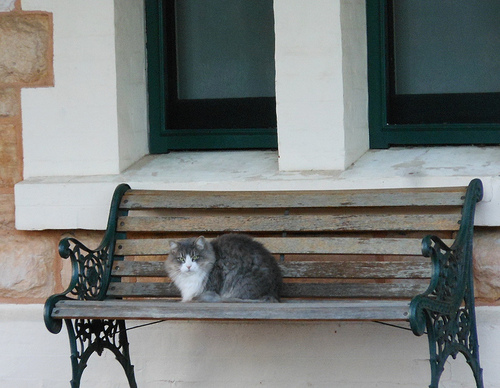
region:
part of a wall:
[368, 179, 384, 193]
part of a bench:
[317, 300, 332, 322]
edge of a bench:
[325, 290, 336, 305]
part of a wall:
[328, 183, 350, 220]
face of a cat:
[183, 254, 205, 275]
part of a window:
[409, 113, 420, 137]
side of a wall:
[326, 140, 337, 157]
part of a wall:
[286, 343, 301, 360]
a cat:
[163, 230, 286, 305]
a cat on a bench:
[163, 232, 289, 307]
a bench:
[43, 180, 494, 386]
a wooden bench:
[36, 180, 490, 385]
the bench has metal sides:
[48, 180, 485, 386]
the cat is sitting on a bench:
[163, 228, 290, 308]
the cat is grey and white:
[162, 229, 289, 306]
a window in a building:
[118, 0, 499, 185]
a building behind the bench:
[3, 5, 492, 386]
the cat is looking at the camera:
[158, 226, 299, 303]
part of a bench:
[407, 275, 427, 298]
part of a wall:
[321, 130, 328, 138]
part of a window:
[388, 124, 411, 186]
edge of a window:
[373, 152, 382, 167]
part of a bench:
[346, 245, 377, 281]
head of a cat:
[193, 253, 222, 268]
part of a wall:
[313, 106, 338, 178]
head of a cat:
[251, 265, 264, 283]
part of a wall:
[108, 145, 126, 152]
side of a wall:
[327, 146, 344, 161]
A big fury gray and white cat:
[163, 228, 293, 306]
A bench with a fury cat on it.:
[32, 180, 495, 387]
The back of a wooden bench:
[25, 178, 498, 242]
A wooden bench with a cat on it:
[27, 167, 462, 387]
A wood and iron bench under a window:
[12, 186, 487, 386]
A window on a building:
[103, 4, 293, 179]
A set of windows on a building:
[90, 3, 498, 156]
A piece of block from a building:
[5, 234, 55, 296]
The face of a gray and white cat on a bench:
[162, 233, 211, 278]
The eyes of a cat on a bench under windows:
[171, 252, 209, 264]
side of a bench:
[436, 310, 446, 334]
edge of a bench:
[376, 303, 386, 313]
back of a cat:
[242, 268, 248, 277]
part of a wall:
[339, 138, 349, 153]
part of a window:
[376, 123, 393, 137]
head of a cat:
[183, 250, 191, 267]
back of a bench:
[328, 258, 347, 283]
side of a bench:
[108, 257, 126, 286]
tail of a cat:
[261, 281, 273, 306]